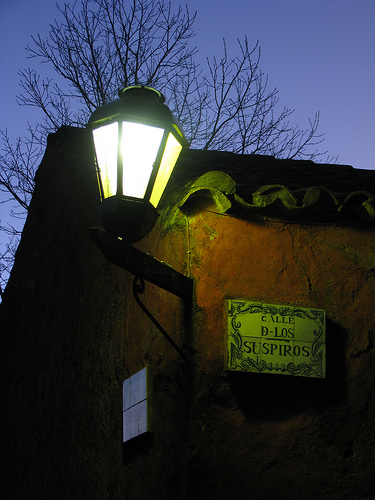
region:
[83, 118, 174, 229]
white light near wall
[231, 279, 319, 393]
black and white sign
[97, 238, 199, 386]
black pole under light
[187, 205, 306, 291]
wall is dark brown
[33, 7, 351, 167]
bare tree behind building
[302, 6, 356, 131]
sky is dark blue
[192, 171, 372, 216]
black rail on roof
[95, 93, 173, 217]
black frame on light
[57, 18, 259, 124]
no leaves on tree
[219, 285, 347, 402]
a sign made of tiles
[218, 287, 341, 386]
the sign is made of six tiles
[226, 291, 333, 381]
there is a border painted on the tiles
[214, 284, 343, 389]
the yellow light shines on the tiles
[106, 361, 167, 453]
this is another sign made of tiles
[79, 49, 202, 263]
this is a lamp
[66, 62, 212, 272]
the light is a bright yellow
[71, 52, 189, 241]
the lamp case is black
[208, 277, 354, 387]
the sign is on the side of a wall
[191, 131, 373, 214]
these are roof shingles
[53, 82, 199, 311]
a lamp on the side of a building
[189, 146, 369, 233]
the roof of a building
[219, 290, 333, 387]
a sign on the side of a building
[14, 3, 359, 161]
the branches of a deciduous tree with no foliage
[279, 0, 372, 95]
a clear blue sky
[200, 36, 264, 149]
a branch on a deciduous tree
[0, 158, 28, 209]
a branch on a deciduous tree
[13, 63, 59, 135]
a branch on a deciduous tree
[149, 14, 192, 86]
a branch on a deciduous tree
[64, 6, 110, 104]
a branch on a deciduous tree